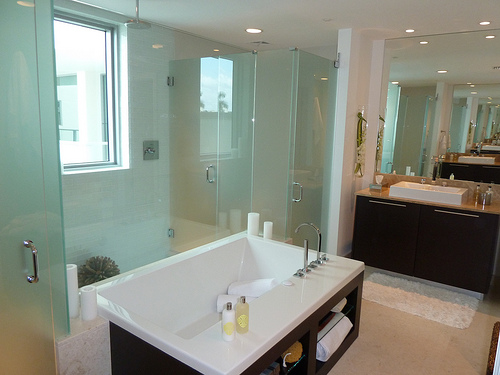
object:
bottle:
[221, 302, 236, 342]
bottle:
[234, 296, 250, 334]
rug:
[361, 272, 479, 330]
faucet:
[420, 162, 447, 187]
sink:
[389, 181, 469, 206]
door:
[291, 47, 337, 252]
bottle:
[221, 296, 249, 342]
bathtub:
[83, 233, 366, 373]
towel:
[67, 263, 100, 321]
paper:
[317, 311, 354, 362]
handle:
[23, 239, 41, 284]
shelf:
[271, 350, 313, 375]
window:
[52, 19, 116, 164]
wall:
[3, 21, 189, 192]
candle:
[369, 174, 389, 192]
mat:
[363, 272, 480, 330]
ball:
[78, 255, 121, 286]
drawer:
[352, 196, 500, 296]